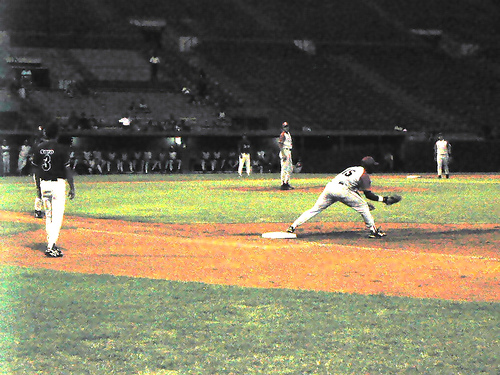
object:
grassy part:
[146, 277, 225, 321]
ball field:
[2, 180, 493, 369]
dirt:
[0, 210, 499, 306]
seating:
[1, 0, 498, 142]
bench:
[71, 148, 263, 173]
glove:
[381, 194, 404, 205]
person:
[32, 121, 76, 257]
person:
[277, 123, 297, 192]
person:
[437, 133, 452, 181]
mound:
[218, 178, 333, 203]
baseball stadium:
[0, 4, 495, 370]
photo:
[4, 7, 492, 319]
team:
[63, 142, 185, 175]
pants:
[286, 185, 373, 232]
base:
[259, 229, 296, 239]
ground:
[2, 170, 497, 372]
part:
[220, 182, 323, 193]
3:
[42, 155, 52, 172]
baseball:
[3, 3, 496, 369]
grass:
[51, 296, 215, 368]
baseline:
[60, 264, 253, 294]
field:
[1, 170, 484, 354]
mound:
[371, 183, 428, 193]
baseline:
[65, 222, 484, 265]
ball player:
[285, 155, 400, 240]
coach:
[237, 131, 252, 178]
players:
[201, 148, 212, 172]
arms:
[66, 168, 77, 202]